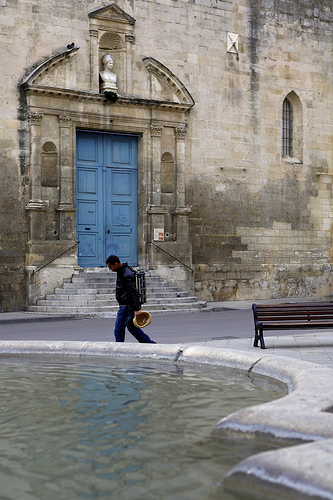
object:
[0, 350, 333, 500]
water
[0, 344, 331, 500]
fountain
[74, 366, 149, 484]
reflection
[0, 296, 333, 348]
sidewalk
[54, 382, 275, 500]
small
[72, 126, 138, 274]
tall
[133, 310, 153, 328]
hat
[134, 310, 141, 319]
hand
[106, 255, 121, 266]
hair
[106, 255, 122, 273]
head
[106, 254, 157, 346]
man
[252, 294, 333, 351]
bench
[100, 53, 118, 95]
statue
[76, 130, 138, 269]
doors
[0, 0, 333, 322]
building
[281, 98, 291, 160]
bars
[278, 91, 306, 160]
window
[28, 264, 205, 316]
steps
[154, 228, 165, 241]
sign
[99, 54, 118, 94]
decoration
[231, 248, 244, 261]
stone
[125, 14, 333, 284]
wall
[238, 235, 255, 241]
stone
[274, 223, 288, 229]
stone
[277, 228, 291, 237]
stone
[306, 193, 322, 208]
stone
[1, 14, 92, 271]
wall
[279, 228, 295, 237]
stone